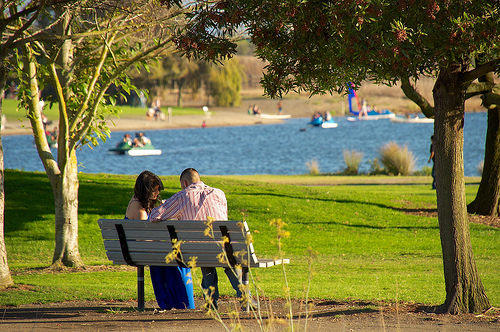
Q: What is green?
A: Grass.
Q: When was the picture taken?
A: Daytime.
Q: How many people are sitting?
A: Two.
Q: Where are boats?
A: In the water.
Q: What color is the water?
A: Blue.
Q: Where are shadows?
A: On the grass.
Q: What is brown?
A: Dirt.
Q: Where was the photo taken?
A: At a park.